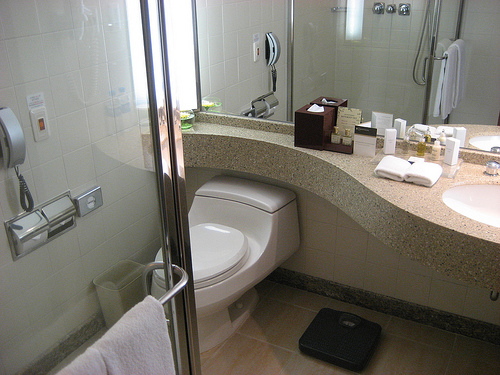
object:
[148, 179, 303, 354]
toilet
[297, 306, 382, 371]
scale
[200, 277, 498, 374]
floor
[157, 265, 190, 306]
towel rack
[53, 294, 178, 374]
towel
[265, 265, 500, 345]
base board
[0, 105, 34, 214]
telephone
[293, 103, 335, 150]
tissue box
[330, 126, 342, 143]
perfume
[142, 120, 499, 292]
counter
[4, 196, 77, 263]
toilet paper holder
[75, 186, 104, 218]
tissue holder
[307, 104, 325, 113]
tissue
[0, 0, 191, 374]
shower door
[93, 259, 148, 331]
trashcan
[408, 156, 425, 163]
soap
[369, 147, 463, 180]
plate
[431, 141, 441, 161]
hair product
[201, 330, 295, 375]
tile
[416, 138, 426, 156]
bottle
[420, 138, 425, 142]
top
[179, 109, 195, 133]
bowl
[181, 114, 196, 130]
liquid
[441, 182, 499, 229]
sink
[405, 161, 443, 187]
towel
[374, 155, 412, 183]
towel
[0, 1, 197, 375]
wall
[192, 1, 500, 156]
mirror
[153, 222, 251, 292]
toilet bowl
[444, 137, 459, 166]
lotion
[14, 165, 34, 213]
cord